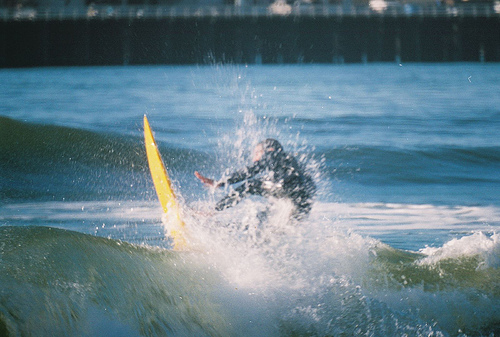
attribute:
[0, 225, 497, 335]
wave — large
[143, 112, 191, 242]
surfboard — yellow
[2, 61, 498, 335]
water — blue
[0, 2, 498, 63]
bridge — large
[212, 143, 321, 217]
wetsuit — black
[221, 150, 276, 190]
arm — extended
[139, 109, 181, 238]
surfboard — yellow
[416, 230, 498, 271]
wave cap —  white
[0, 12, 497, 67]
wall — black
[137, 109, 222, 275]
surfboard — Yellow 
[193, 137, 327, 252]
surfer — falling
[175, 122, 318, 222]
armout —  regain balance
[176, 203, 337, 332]
water —   splashing 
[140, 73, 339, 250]
sufer — ride good size waves 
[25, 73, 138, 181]
waves — Series ,  rolling in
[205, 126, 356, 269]
surfer — wetsuit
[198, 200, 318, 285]
foam — White, breaking 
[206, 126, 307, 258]
people — watching , background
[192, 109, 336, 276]
surfer — Bright sun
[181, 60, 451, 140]
water — blue , ripples 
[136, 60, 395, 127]
water — ripples , blue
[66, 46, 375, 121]
water — blue, ripples 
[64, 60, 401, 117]
water — ripples , blue 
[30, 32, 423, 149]
water — blue , ripples 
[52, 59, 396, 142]
water — ripples , blue 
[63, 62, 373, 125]
water — blue , ripples